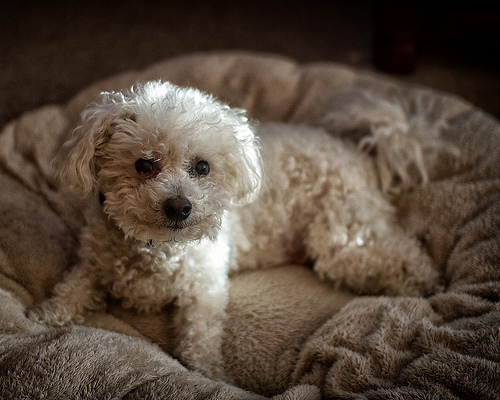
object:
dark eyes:
[134, 158, 153, 174]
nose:
[163, 195, 192, 220]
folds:
[293, 136, 500, 399]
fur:
[129, 83, 228, 130]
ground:
[0, 0, 500, 400]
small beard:
[141, 230, 210, 249]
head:
[49, 80, 267, 246]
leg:
[174, 259, 231, 374]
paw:
[413, 262, 440, 295]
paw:
[172, 343, 225, 382]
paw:
[25, 295, 64, 327]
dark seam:
[81, 302, 184, 367]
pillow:
[1, 51, 500, 399]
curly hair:
[48, 79, 266, 209]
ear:
[51, 90, 132, 199]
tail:
[319, 85, 462, 198]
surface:
[0, 52, 499, 399]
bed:
[0, 52, 499, 399]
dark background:
[0, 2, 500, 123]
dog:
[26, 79, 460, 384]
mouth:
[127, 211, 214, 234]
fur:
[135, 145, 162, 161]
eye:
[195, 160, 210, 175]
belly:
[225, 238, 302, 278]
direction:
[319, 87, 462, 197]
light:
[143, 78, 262, 290]